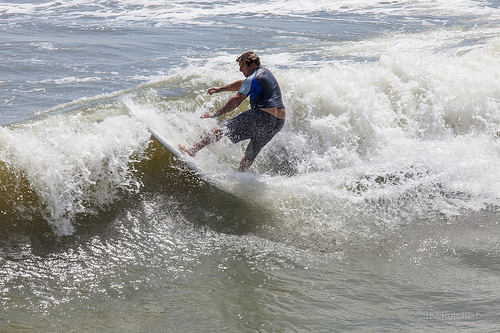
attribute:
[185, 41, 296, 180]
man — surfing, exposed, curving, extending, wet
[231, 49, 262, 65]
hair — dark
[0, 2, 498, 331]
water — wavy, blue, gray, calm, foaming, high, yellowish, falling, glistening, white, spraying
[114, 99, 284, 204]
board — white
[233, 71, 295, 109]
shirt — blue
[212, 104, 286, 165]
shorts — dark